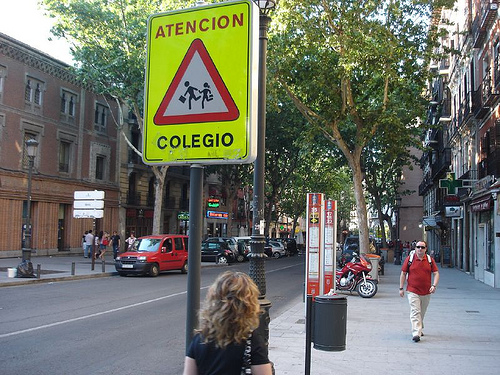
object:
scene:
[1, 1, 486, 369]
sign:
[437, 178, 468, 189]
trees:
[266, 1, 461, 259]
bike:
[336, 252, 378, 298]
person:
[398, 239, 440, 343]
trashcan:
[311, 294, 348, 351]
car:
[113, 234, 191, 275]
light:
[15, 138, 38, 278]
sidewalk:
[267, 257, 485, 373]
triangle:
[151, 39, 244, 124]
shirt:
[185, 327, 269, 374]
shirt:
[401, 251, 440, 295]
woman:
[184, 268, 274, 374]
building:
[0, 31, 190, 261]